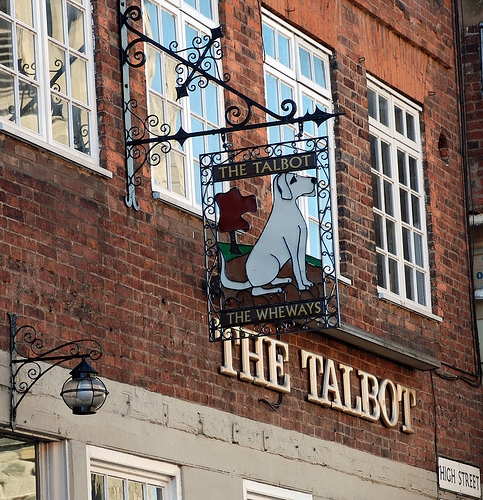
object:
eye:
[289, 174, 298, 185]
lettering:
[212, 318, 417, 435]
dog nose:
[311, 177, 317, 185]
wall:
[92, 267, 178, 362]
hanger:
[9, 315, 103, 412]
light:
[59, 370, 109, 415]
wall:
[2, 202, 101, 244]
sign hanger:
[122, 5, 346, 203]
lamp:
[8, 313, 109, 430]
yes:
[194, 131, 343, 339]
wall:
[146, 249, 209, 341]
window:
[366, 70, 444, 321]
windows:
[134, 0, 230, 224]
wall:
[379, 18, 480, 84]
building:
[441, 362, 481, 436]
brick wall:
[2, 202, 44, 262]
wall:
[339, 441, 404, 497]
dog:
[217, 172, 319, 297]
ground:
[47, 227, 176, 318]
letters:
[440, 465, 444, 480]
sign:
[199, 135, 340, 343]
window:
[260, 29, 341, 285]